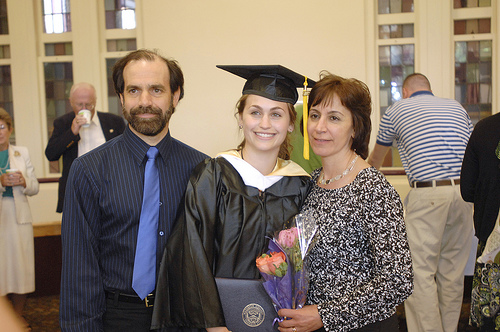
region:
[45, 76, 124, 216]
An old man drinking from a white cup.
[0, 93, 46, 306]
A woman wearing glasses and a white dress.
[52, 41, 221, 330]
A man wearing a blue tie.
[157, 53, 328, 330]
A young woman wearing a graduation gown.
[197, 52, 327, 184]
A graduation cap with yellow tassles.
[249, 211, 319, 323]
A group of four pink roses.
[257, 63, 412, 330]
A woman holding flowers.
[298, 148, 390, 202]
A silver necklace that is worn by the woman.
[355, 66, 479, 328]
A man wearing a blue and white stripped shirt.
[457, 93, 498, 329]
A lady wearing a green coat.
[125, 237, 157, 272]
part of a blue tie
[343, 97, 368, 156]
hair of a woman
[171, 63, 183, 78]
hair of a woman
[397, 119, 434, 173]
part of a stripped shirt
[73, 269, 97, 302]
part of a shirt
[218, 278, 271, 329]
this is graduation document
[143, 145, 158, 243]
this is a blue tie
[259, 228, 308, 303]
these are flowers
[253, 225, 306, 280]
the flowers are pink in color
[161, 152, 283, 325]
this is the graduation gown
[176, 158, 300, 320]
the gown is black and gold in color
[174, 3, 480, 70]
these is a building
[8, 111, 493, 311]
these are people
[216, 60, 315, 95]
this is graduation cap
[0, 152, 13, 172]
this is a necklace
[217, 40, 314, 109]
the cap is black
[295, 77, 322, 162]
the tassle is yellow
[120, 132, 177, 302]
the tie is blue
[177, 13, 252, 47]
the wall is white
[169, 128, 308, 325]
the gown is black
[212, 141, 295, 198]
the collar is white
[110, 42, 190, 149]
the man has a beard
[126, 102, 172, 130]
the beard is black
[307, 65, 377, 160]
the hair is brown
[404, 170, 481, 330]
the pants are brown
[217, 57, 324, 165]
A BLACK GRADUATION CAP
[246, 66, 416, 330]
A WOMAN HOLDING FLOWERS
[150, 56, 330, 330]
A WOMAN HOLDING A DIPLOMA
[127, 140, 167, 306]
A BLUE NECK TIE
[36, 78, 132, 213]
AN OLDER MAN DRINKING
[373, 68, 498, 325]
A MAN IN THE BACKGROUND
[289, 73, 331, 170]
A YELLOW TASSLE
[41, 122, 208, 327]
A BLUE PINSTRIPED SHIRT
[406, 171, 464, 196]
A MANS BELT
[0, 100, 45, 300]
A WOMAN HOLDING A CUP